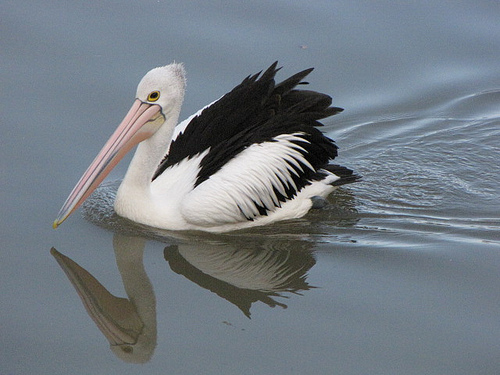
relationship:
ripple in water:
[316, 79, 500, 250] [5, 2, 497, 373]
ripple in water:
[321, 79, 485, 154] [5, 2, 497, 373]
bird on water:
[52, 59, 363, 234] [112, 244, 281, 361]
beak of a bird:
[51, 98, 163, 230] [86, 58, 348, 239]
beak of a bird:
[51, 98, 163, 230] [134, 71, 376, 225]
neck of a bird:
[127, 130, 175, 203] [46, 72, 354, 234]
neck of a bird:
[114, 116, 179, 215] [75, 70, 379, 254]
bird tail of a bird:
[242, 59, 345, 127] [23, 28, 433, 304]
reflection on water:
[49, 230, 320, 365] [5, 2, 497, 373]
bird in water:
[36, 56, 360, 239] [5, 2, 497, 373]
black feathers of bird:
[265, 68, 312, 104] [36, 56, 360, 239]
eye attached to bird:
[147, 90, 161, 102] [36, 56, 360, 239]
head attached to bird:
[51, 55, 187, 257] [42, 44, 343, 264]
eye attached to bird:
[146, 89, 166, 100] [36, 56, 360, 239]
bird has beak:
[52, 59, 363, 234] [53, 104, 157, 244]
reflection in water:
[47, 226, 324, 367] [5, 2, 497, 373]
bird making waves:
[52, 59, 363, 234] [333, 95, 497, 266]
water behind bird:
[5, 2, 497, 373] [52, 59, 363, 234]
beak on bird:
[52, 97, 164, 227] [30, 54, 401, 265]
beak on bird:
[51, 98, 163, 230] [53, 56, 363, 230]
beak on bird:
[51, 98, 163, 230] [1, 2, 495, 374]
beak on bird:
[51, 98, 163, 230] [43, 51, 380, 258]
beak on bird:
[52, 97, 164, 227] [39, 60, 372, 264]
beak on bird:
[52, 97, 164, 227] [36, 56, 360, 239]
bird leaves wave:
[52, 59, 363, 234] [386, 114, 491, 227]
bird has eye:
[52, 59, 363, 234] [147, 90, 161, 102]